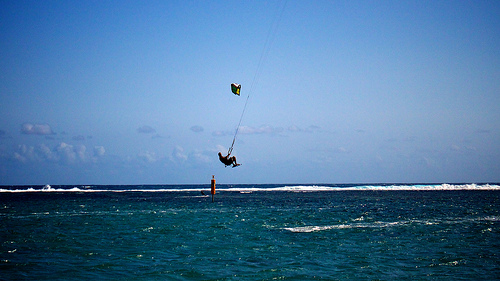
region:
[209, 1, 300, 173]
Man paragliding in the air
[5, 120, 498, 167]
Clouds drifting through the sky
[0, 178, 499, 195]
Wave breaking in the distance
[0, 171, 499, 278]
Ocean extending to the horizon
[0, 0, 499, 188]
Blue boundless sky dotted by clouds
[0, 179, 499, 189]
Horizon line dividing the unknown from the known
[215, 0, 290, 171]
Man taking to the sky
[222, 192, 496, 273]
Ripples characterizing the ocean's surface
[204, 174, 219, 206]
Some sort of marker or buoy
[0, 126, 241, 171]
Clouds fading into the distance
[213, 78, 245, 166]
Parasailing man above water.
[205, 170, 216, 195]
Red object in water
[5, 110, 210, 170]
Clouds are in distance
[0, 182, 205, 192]
White waves near horizon.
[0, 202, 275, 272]
Calm water in foreground.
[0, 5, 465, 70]
Clear skies above sea.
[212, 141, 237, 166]
Man is above water.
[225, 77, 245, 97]
Sail is in the air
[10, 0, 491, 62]
Skies are clear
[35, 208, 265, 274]
Clear Water is still.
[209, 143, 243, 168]
surfer in mid air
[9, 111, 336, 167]
line of clouds above water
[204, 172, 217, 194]
orange buoy in ocean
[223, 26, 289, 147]
rope man is holding ton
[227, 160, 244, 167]
board man is riding on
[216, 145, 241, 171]
man holding onto rope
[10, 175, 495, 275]
waters man is surfing in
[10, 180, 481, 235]
white foam in ocean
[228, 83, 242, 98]
colored object in sky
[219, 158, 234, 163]
black life vest of man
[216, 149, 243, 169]
guy in the air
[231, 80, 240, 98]
bright kite in the air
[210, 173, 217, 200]
orange buoy in the water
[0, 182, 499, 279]
deep blue ocean water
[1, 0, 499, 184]
blue mostly clear sky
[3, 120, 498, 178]
gathering of clouds in the sky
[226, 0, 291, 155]
line attached to guy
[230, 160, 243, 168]
board on guy's feet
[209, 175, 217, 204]
skinny orange buoy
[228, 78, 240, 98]
brightly colored wind catcher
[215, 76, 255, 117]
kite flown in sky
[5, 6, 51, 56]
white clouds in blue sky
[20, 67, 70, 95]
white clouds in blue sky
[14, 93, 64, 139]
white clouds in blue sky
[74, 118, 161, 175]
white clouds in blue sky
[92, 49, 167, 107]
white clouds in blue sky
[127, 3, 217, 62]
white clouds in blue sky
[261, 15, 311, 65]
white clouds in blue sky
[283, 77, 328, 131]
white clouds in blue sky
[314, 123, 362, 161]
white clouds in blue sky